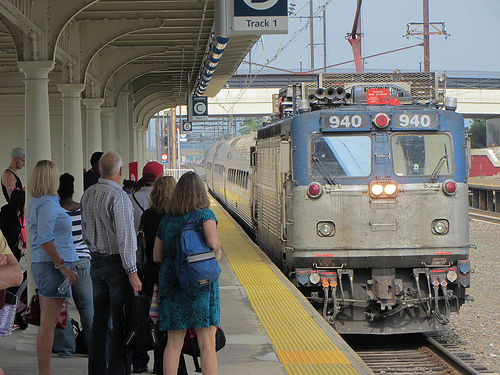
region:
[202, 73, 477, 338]
Train pulling into station.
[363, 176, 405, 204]
Headlights on front of train.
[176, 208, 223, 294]
Woman carrying blue backpack over shoulder.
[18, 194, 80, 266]
Woman dressed in light blue blouse.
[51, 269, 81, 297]
Woman carrying water bottle in hand.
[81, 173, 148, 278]
Man dressed in long sleeve white and blue check shirt.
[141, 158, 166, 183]
Man wearing red cap on head.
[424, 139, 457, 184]
Windshield wiper on front window of train.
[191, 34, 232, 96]
Lights mounted in ceiling of train station.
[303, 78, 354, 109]
Horns to top of train.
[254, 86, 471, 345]
a blue and silver train engine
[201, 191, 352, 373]
a long yellow line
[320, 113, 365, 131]
train engine number 940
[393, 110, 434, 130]
train engine number 940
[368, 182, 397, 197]
a train engine headlight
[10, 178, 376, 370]
a train boarding platform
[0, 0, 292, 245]
overhead train platform shelter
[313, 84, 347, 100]
train engine horns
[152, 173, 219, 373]
a woman standing on platform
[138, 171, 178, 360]
a woman standing on platform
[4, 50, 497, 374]
a crowd of people waiting for a train at a train platform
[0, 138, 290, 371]
the crowd of people waiting for the train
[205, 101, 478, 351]
the train the people are waiting for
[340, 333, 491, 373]
train tracks the train is running on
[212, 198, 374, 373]
yellow caution area of the train platform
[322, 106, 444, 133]
the number of the train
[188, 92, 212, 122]
sign indicating the train platform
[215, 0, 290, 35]
bottom of the sign indicating the train platform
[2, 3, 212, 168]
arched awning of the train platform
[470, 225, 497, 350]
gravel on the ground behind the train and its tracks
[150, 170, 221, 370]
woman holding a backpack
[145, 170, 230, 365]
woman wearing a dress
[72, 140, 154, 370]
man wearing a shirt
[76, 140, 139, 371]
man wearing blue jeans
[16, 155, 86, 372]
woman wearing blue shirt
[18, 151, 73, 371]
woman wearing blue jean shorts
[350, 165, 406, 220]
light on a train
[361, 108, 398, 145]
light on a train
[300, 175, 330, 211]
light on a train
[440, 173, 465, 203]
light on a train